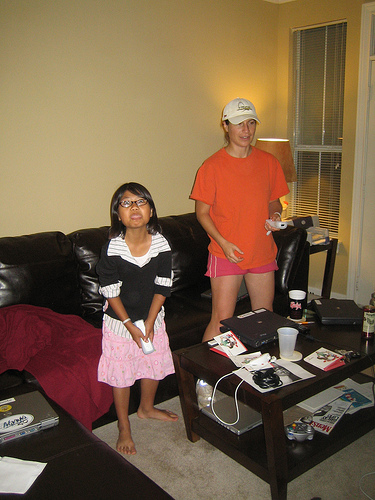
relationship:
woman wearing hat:
[199, 90, 287, 303] [222, 98, 270, 124]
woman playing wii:
[199, 90, 287, 303] [266, 217, 295, 229]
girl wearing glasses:
[94, 180, 178, 452] [114, 196, 148, 212]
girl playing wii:
[93, 276, 172, 312] [266, 217, 295, 229]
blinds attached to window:
[299, 97, 339, 117] [283, 2, 343, 217]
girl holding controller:
[93, 276, 172, 312] [117, 321, 153, 355]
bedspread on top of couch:
[0, 303, 115, 428] [0, 222, 79, 394]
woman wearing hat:
[199, 90, 287, 303] [222, 96, 262, 123]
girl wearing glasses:
[93, 276, 172, 312] [114, 196, 148, 212]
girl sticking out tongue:
[93, 276, 172, 312] [129, 212, 143, 222]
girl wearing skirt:
[93, 276, 172, 312] [96, 319, 174, 388]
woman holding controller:
[199, 90, 287, 303] [117, 321, 153, 355]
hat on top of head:
[222, 98, 270, 124] [217, 124, 264, 130]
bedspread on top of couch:
[44, 322, 86, 362] [22, 252, 71, 284]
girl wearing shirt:
[93, 276, 172, 312] [112, 265, 113, 266]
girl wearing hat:
[93, 276, 172, 312] [222, 96, 262, 123]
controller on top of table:
[117, 321, 153, 355] [210, 334, 356, 412]